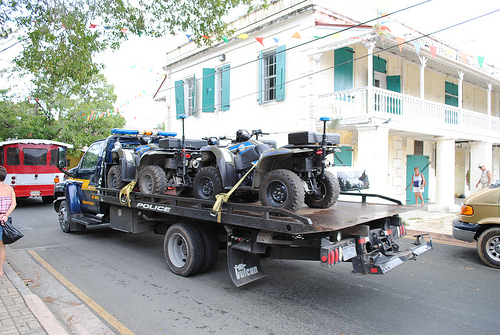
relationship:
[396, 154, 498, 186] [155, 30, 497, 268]
people in front of building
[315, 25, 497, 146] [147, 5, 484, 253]
balcony in front of building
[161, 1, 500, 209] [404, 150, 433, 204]
building with door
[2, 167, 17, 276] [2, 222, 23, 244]
woman holding black bag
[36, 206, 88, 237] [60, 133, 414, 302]
wheel of truck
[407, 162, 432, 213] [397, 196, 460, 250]
woman at sidewalk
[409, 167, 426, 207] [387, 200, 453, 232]
woman at sidewalk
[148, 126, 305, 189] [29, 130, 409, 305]
bikes on truck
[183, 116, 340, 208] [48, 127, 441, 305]
bike on truck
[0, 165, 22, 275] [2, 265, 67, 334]
woman on sidewalk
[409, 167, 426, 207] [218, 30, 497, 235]
woman in front of building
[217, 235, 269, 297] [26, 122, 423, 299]
flap on truck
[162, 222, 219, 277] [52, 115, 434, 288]
wheel on trailer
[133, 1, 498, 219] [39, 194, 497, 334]
building on left side of road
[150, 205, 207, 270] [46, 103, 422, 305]
wheel of truck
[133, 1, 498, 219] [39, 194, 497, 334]
building near road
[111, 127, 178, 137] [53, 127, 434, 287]
lights on truck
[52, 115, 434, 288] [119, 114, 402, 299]
trailer on trailer